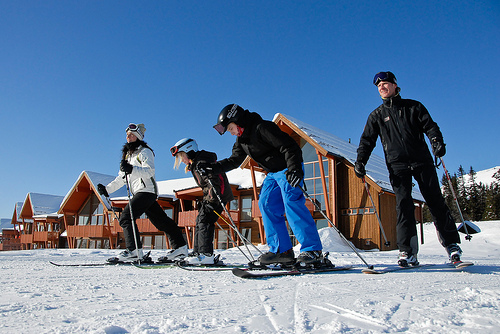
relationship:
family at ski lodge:
[103, 106, 433, 260] [29, 196, 100, 247]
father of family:
[350, 58, 461, 266] [103, 106, 433, 260]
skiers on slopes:
[114, 131, 374, 301] [1, 281, 85, 324]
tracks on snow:
[109, 292, 193, 331] [336, 285, 407, 304]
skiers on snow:
[114, 131, 374, 301] [336, 285, 407, 304]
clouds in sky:
[454, 109, 463, 150] [156, 14, 214, 31]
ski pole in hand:
[188, 180, 250, 251] [349, 167, 380, 186]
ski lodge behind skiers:
[29, 196, 100, 247] [114, 131, 374, 301]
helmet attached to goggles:
[211, 107, 239, 122] [366, 71, 392, 79]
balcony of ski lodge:
[66, 204, 102, 228] [29, 196, 100, 247]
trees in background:
[455, 182, 494, 213] [461, 161, 494, 183]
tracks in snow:
[109, 292, 193, 331] [336, 285, 407, 304]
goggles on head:
[366, 71, 392, 79] [348, 60, 405, 108]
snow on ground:
[336, 285, 407, 304] [348, 292, 408, 316]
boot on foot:
[305, 243, 318, 273] [397, 229, 423, 268]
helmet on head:
[211, 107, 239, 122] [348, 60, 405, 108]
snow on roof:
[336, 285, 407, 304] [159, 176, 194, 199]